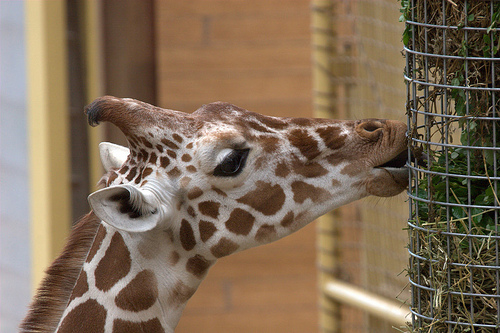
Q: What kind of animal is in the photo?
A: Giraffe.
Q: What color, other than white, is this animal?
A: Brown.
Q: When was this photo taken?
A: During the day.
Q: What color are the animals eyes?
A: Black.